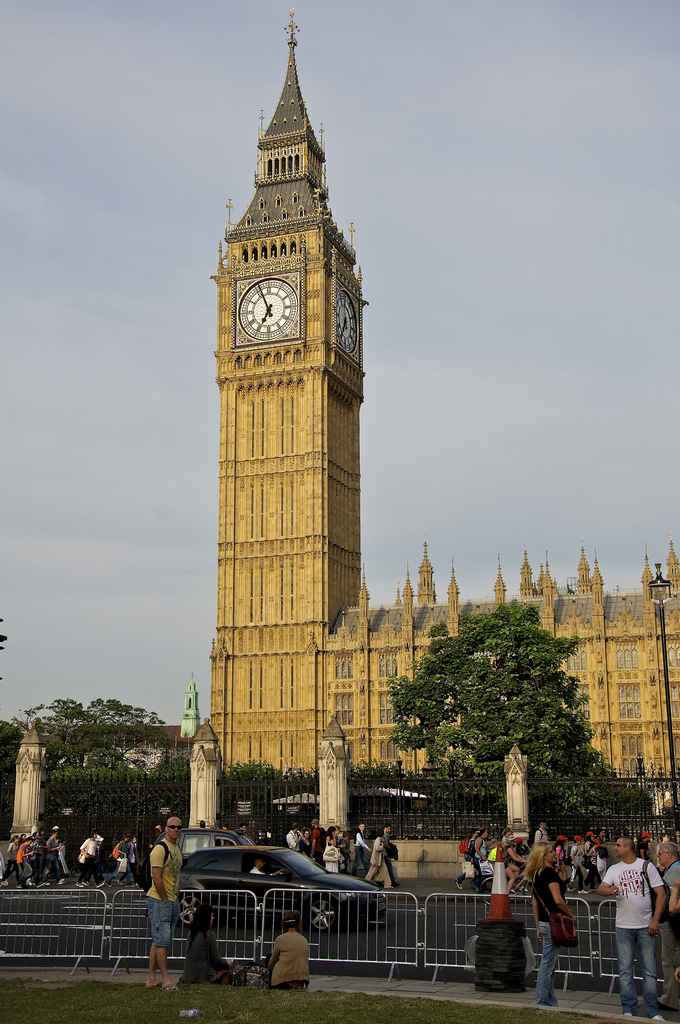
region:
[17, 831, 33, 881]
Person is walking on the sidewalk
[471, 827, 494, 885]
Person is walking on the sidewalk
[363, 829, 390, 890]
Person is walking on the sidewalk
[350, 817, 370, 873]
Person is walking on the sidewalk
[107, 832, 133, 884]
Person is walking on the sidewalk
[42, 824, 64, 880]
Person is walking on the sidewalk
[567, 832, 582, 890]
Person is walking on the sidewalk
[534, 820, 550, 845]
Person is walking on the sidewalk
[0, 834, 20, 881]
Person is walking on the sidewalk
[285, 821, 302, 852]
Person is walking on the sidewalk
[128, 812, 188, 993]
Man carrying a black backpack.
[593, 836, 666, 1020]
Man wearing a white t-shirt.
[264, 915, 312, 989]
Man wearing a brown jacket.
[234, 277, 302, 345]
White clock with black dials.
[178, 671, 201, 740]
Small green church steeple.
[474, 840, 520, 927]
Orange and white traffic cone.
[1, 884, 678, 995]
Metal silver fence barrier.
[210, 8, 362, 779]
Tall brown brick tower.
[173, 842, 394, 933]
Black car driving on the road.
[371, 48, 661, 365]
Sky is blue color.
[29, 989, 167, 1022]
Grass is green color.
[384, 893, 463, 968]
Road is grey color.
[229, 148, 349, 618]
Tower is brown color.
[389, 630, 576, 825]
Tree is green color.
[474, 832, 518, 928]
Cone is orange and white color.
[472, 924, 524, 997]
Can is black color.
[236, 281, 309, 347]
Clock is black and white color.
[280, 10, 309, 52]
Direction pointer is in top of tower.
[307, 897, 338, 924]
front tire of the car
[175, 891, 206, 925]
back tire of the car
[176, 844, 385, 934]
it is a black car in the street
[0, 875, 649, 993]
it is a grey rail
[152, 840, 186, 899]
the shirt is yellow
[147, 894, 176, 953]
the shorts are blue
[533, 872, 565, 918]
the shirt is black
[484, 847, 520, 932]
it is an orange cone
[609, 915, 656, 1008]
the jeans are blue